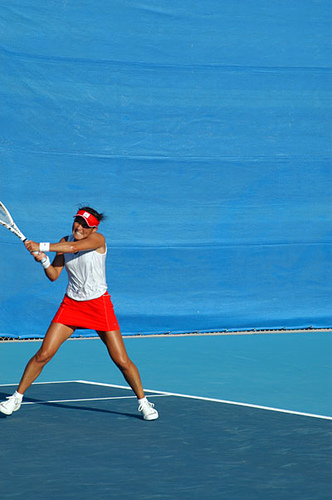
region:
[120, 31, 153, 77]
part of a chart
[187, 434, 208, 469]
part of a court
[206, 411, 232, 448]
part of a floor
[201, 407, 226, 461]
part of a floor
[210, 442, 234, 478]
part of a field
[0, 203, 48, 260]
white tennis racket held by the woman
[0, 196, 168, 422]
woman swinging a tennis racket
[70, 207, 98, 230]
red and white hat on the woman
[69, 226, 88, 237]
demples on the woman's face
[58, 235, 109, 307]
white sleeveless shirt on the woman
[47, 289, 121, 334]
red skirt on the woman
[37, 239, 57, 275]
white armbands on the woman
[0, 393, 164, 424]
white tennis shoes on the woman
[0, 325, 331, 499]
green tennis court with white lines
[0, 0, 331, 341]
a blue wall around the tennis court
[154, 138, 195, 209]
part of a banner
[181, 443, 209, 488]
part of a floor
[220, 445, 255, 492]
part of a court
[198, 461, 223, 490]
part of a court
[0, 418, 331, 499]
bottom half of floor of the tennis court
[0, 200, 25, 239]
female tennis player tennis racket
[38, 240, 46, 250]
ristband of female tennis player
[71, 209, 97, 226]
female tennis player red visor cap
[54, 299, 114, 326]
female tennis player red skirt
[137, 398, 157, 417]
female tennis player left tennis shoe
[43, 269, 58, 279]
female tennis tennis player elbow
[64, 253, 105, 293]
female tennis white player blouse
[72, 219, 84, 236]
intense tennis player face hitting hard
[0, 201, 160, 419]
female tennis player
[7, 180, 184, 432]
A woman playing tennis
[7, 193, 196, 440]
A woman holding a tennis racket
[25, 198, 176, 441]
A woman wearing a red visor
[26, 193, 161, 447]
A woman wearing a white shirt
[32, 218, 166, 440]
A woman wearing white wrist bands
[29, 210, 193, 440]
A woman wearing a red tennis skirt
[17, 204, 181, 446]
A woman wearing white sneakers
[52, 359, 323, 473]
A blue tennis court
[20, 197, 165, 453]
A woman on a tennis court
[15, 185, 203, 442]
A woman on a blue tennis court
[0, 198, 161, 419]
woman holding a tennis racket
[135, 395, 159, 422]
white sock and shoe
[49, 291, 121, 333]
short bright red skirt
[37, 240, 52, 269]
two wrist sweatbands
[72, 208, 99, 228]
red and white sun visor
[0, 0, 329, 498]
blue tennis court and blue wall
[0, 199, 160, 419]
woman with very tan skin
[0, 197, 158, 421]
woman wearing a white shirt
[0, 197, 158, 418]
woman wearing a red skirt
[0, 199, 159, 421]
tan woman playing tennis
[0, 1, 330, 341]
wall of blue fabric